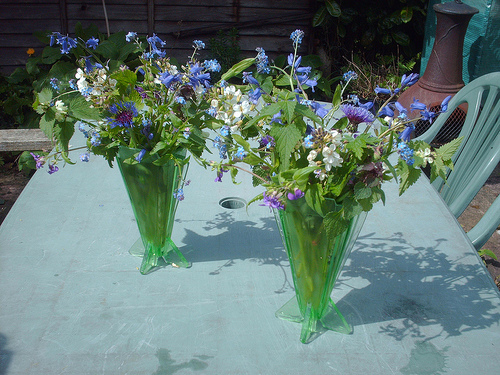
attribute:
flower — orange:
[26, 47, 34, 54]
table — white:
[136, 282, 259, 367]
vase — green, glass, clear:
[278, 196, 363, 346]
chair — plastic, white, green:
[402, 71, 496, 256]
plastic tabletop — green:
[4, 89, 494, 374]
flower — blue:
[396, 72, 418, 86]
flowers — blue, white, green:
[74, 29, 409, 274]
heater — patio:
[387, 1, 477, 135]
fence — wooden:
[3, 2, 324, 101]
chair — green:
[408, 68, 499, 248]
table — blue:
[5, 94, 498, 374]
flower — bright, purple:
[253, 175, 308, 233]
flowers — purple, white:
[321, 143, 341, 160]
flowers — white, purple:
[157, 69, 188, 90]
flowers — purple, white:
[290, 26, 305, 49]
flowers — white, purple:
[286, 185, 306, 202]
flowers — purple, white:
[73, 65, 88, 83]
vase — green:
[274, 194, 364, 336]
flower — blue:
[105, 99, 120, 116]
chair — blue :
[458, 54, 498, 244]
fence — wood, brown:
[16, 8, 334, 113]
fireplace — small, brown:
[390, 2, 473, 154]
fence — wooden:
[52, 0, 240, 80]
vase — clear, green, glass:
[269, 193, 357, 343]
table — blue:
[64, 267, 165, 346]